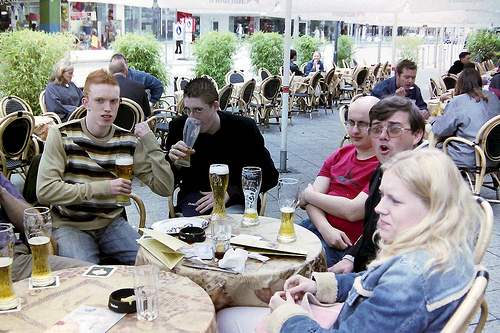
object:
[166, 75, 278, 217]
man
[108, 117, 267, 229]
beer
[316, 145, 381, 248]
shirt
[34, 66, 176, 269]
boy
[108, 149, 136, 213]
glass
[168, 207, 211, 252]
ashtray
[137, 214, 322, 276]
table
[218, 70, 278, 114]
chairs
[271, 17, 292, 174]
pole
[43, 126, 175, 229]
sweater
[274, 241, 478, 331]
jacket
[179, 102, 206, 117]
eyeglasses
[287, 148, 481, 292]
girl